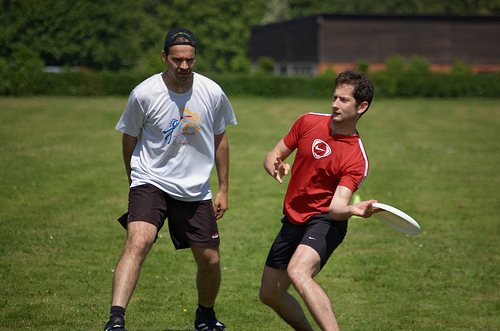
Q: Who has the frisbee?
A: Man with the red shirt.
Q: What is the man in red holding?
A: A frisbee.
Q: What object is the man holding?
A: Frisbee.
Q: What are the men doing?
A: Playing frisbee.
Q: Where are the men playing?
A: In a park.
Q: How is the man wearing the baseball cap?
A: Backwards.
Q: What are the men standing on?
A: Grass.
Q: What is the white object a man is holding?
A: Frisbee.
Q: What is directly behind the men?
A: Bushes.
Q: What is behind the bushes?
A: Building.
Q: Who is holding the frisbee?
A: Man in red shirt.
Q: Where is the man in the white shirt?
A: Next to the man in the red shirt.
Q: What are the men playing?
A: Frisbee.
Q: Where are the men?
A: Park.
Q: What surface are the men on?
A: Grass.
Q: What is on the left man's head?
A: Hat.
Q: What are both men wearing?
A: Shorts.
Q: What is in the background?
A: Hedge.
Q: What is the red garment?
A: T Shirt.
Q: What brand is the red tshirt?
A: Nike.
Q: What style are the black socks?
A: Crew.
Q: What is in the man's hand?
A: A disk.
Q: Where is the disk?
A: In the man's hand.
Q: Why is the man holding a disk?
A: To play frisbee.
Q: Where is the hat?
A: On the left man's head.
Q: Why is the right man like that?
A: To throw a disk.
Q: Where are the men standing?
A: In a field.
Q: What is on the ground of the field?
A: Grass.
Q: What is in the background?
A: Trees.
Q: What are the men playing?
A: Frisbee.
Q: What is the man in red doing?
A: Throwing the frisbee.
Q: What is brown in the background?
A: Building.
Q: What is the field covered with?
A: Grass.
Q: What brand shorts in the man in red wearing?
A: Nike.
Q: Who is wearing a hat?
A: Man on left.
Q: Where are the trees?
A: Behind the field.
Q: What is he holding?
A: A frisbee.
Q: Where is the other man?
A: Next to his friend.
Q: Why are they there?
A: Throwing a frisbee.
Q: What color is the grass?
A: Green.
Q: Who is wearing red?
A: The man on the right.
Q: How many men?
A: 2.